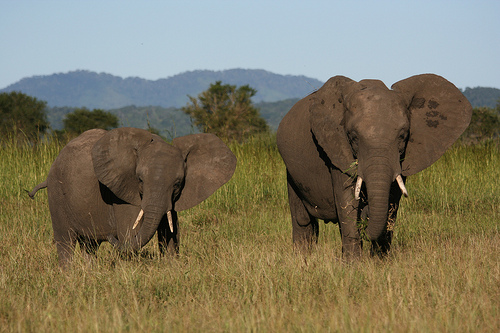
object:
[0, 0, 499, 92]
skies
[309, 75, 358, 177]
ear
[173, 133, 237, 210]
ear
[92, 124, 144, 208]
ear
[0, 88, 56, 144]
trees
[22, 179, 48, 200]
tail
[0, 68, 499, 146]
hill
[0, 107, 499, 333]
ground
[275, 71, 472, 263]
elephant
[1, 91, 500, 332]
grasslands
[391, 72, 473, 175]
ear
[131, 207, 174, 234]
elephant tusks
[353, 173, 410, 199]
elephant tusks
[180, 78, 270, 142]
tree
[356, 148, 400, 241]
trunk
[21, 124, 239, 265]
elephant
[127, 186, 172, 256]
trunk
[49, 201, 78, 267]
leg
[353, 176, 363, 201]
tusk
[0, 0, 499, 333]
background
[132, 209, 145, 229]
tusk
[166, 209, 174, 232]
tusk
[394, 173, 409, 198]
tusk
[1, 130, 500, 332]
grass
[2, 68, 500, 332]
field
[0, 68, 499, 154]
forest